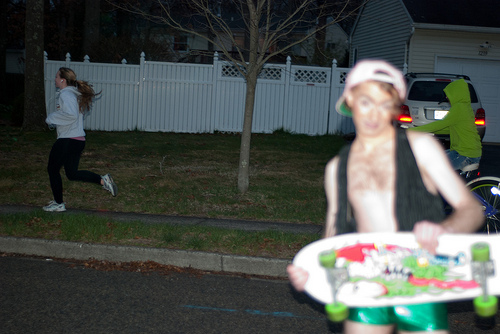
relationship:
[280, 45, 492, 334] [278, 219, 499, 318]
boy holding skateboard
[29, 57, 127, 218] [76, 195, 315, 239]
woman running on driveway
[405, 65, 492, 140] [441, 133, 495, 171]
car parked in driveway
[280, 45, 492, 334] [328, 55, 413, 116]
boy wearing hat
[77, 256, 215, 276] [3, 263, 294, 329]
leaves on ground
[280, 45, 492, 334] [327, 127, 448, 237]
boy wearing vest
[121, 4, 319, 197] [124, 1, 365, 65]
tree without leaves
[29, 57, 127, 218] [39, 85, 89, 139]
runner in white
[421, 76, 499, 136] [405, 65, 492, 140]
biker with sweatshirt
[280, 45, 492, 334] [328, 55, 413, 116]
boy wit pink hat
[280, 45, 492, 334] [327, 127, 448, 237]
boy wearing black vest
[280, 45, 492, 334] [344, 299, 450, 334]
boy wears bright green shorts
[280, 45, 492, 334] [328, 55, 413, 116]
boy wears pink cap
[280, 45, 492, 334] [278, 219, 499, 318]
boy carrying a skateboard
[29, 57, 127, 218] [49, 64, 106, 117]
woman with dark blond hair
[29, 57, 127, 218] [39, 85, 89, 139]
woman with white jacket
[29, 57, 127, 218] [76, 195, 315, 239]
woman jogging down driveway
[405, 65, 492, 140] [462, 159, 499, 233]
child riding bicycle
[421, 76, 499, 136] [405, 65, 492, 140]
biker in green hoodie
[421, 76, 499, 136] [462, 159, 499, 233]
biker riding bicycle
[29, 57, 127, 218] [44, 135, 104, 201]
woman wearing pants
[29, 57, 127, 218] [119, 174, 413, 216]
woman wearing shoes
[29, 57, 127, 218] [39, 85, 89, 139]
woman wearing jacket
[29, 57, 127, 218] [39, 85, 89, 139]
woman wearing white jacke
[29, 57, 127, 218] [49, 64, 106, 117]
woman has hair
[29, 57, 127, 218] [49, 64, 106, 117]
woman has brown hair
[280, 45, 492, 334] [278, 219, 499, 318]
boy has skateboard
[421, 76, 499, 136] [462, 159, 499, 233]
biker riding bike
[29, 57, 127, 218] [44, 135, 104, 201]
woman wearing black pants